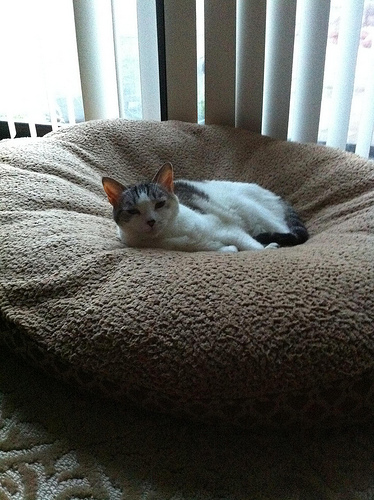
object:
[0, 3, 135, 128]
sunlight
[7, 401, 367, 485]
rug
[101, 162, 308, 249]
cat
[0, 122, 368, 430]
bed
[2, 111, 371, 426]
seat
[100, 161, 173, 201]
ears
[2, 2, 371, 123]
blinds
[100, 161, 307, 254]
tabby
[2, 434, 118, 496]
design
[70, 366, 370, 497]
shadow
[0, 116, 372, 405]
pet pillow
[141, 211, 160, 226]
nose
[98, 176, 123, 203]
ear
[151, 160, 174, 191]
ear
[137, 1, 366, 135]
vertical blinds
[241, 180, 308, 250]
back end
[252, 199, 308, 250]
tail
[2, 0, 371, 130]
window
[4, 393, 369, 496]
carpet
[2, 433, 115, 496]
pattern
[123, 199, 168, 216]
eyes